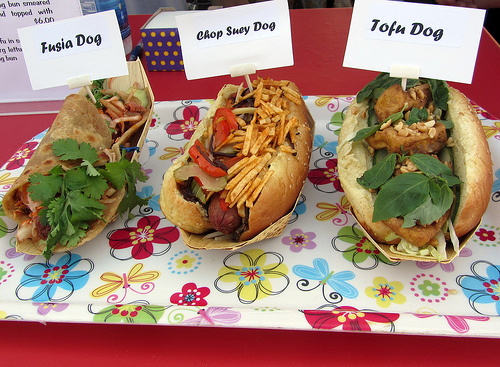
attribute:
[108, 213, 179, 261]
flower — red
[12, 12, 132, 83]
sign — Fugia dog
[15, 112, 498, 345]
tray — serving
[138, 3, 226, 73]
box — purple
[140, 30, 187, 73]
dots — yellow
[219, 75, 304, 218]
potatoes — yellow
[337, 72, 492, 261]
hot dog — tofu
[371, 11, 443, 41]
letters — black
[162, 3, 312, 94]
sign — Chop Suey Dog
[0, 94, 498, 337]
serving tray — floral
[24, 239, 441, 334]
flowers — yellow, blue, purple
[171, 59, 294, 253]
hot dog — chop suey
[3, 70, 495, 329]
tray — serving, floral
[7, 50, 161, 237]
hot dog — Fusia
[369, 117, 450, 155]
marinated — cooked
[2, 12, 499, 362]
serving table — decorative, red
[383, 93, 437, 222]
dog — tofu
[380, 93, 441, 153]
tofu — marinated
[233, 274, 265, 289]
flower — yellow